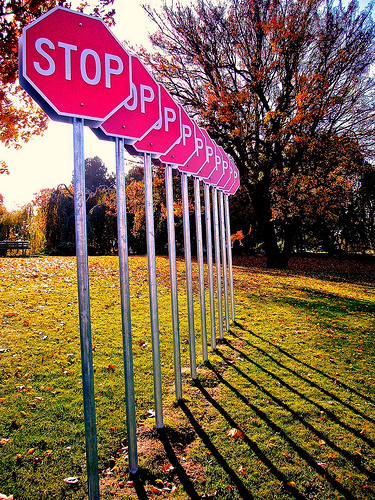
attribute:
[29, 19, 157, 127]
sign — red, white, stop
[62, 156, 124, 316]
pole — metal, grey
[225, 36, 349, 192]
trees — brown, large, orange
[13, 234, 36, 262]
bench — far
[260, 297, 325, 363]
grass — green, brown